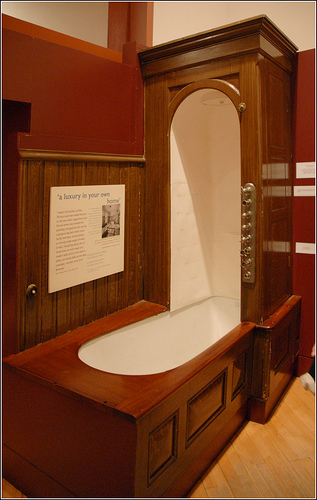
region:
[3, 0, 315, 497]
people's palace, scotland, bathroom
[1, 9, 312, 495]
bathroom is 'fitted' bathroom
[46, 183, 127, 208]
'a luxury in your own home'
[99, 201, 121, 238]
a blurry b+w photo of a room in a palace beneath the word 'home'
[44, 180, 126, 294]
exhibit sign on wall looks like advertisement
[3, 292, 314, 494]
bathtub encased in a reddish orange wood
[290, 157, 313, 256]
wall has several small exhibit signs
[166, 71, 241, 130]
rounded arch over what may be shower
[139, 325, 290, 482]
four panels in wooden bathtub case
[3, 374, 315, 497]
floor is o worn yellowish hardwood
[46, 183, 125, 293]
A sign on the wall.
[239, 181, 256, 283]
Knobs on a wall.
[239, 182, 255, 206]
Two knobs on a wall.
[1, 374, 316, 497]
A hard wood floor.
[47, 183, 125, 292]
A sign with words.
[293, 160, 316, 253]
Three signs on a wall.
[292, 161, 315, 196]
Two signs on a wall.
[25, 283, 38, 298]
A button on a wall.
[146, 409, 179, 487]
A panel on a wall.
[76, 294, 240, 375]
A white bath tub.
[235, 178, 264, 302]
Multiple silver nozzles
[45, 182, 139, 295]
A white sign with writing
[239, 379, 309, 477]
Floors made of wood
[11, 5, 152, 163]
White, red, and orange walls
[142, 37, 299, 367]
Tall brown wooden shower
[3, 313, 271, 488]
The white tub is surrounded by wood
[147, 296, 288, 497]
The wood of the tub is darker than the flooring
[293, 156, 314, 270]
There are three white signs on the red wall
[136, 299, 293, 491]
The wooden tub has designs on the side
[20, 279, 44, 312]
A small round white button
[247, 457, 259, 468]
the floors are wooden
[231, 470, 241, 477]
the floors are wooden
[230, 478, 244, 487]
the floors are wooden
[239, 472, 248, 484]
the floors are wooden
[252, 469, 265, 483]
the floors are wooden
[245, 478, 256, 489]
the floors are wooden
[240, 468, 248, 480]
the floors are wooden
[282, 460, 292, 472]
the floors are wooden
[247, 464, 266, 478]
the floors are wooden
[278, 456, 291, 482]
the floors are wooden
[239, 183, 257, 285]
long grey metal knob pannel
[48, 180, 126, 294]
historic newspaper hung on wall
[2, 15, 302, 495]
large brown wooden frame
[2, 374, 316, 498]
the flooring is hardwood floors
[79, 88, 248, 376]
The inside is curved and white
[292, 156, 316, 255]
Three pieces of paper hang on wall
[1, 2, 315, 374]
Walls are painted red, white, orange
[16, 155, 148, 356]
wood panneling is covering wall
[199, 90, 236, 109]
White circle at top of unit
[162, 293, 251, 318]
There is a seam difference in the white